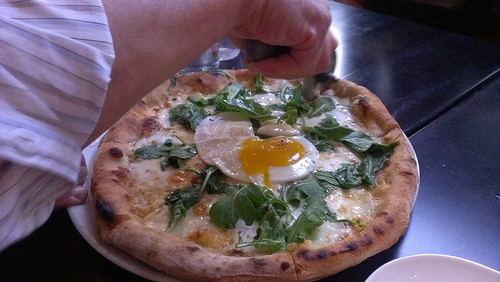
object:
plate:
[363, 253, 498, 281]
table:
[0, 0, 499, 282]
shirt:
[0, 0, 117, 251]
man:
[0, 0, 339, 250]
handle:
[242, 39, 281, 62]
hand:
[225, 0, 338, 80]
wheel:
[90, 69, 418, 282]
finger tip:
[70, 185, 90, 205]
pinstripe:
[0, 4, 81, 238]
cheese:
[324, 186, 379, 222]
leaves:
[237, 208, 289, 251]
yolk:
[239, 137, 305, 189]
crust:
[89, 65, 419, 281]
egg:
[191, 108, 320, 189]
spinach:
[162, 167, 226, 233]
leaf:
[335, 145, 394, 187]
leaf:
[304, 115, 350, 151]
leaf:
[171, 99, 201, 132]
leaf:
[160, 189, 203, 223]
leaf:
[278, 168, 341, 208]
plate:
[68, 128, 420, 281]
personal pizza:
[90, 66, 420, 281]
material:
[0, 0, 116, 250]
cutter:
[242, 30, 337, 102]